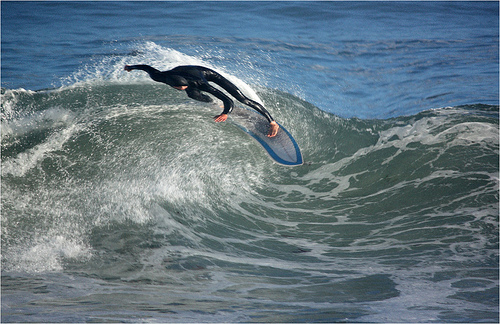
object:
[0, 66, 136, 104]
crest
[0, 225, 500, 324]
sea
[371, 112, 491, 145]
foam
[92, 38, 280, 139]
waves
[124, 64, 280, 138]
man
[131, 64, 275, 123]
wet suit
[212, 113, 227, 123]
hand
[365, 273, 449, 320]
foam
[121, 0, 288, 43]
water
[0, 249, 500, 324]
water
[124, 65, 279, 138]
surfer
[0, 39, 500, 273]
wave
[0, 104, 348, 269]
trough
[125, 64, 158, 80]
arm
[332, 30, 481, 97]
water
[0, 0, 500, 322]
ocean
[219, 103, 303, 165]
surfboard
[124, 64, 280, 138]
swimmer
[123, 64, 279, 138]
person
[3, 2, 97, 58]
water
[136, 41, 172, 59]
spray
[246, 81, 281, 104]
wake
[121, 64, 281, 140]
pose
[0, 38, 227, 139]
wave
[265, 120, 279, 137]
foot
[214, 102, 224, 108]
foot